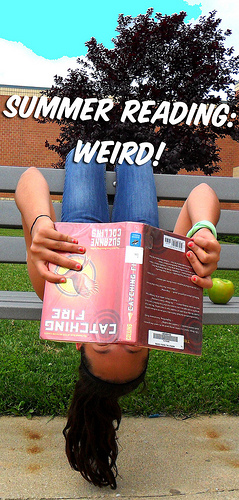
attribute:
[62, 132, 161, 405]
girl — upside down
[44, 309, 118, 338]
book — red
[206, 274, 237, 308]
apple — green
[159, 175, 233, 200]
bench — gray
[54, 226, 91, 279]
nails — pink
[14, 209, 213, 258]
bracelet — green, black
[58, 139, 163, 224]
jeans — blue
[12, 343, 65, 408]
grass — green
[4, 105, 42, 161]
wall — orange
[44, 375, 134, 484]
hair — black